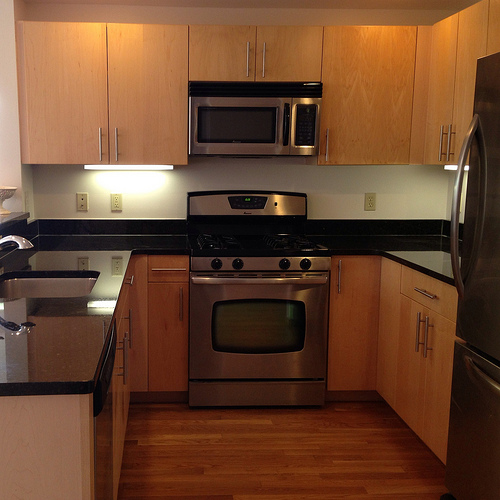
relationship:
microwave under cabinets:
[185, 82, 323, 158] [181, 27, 323, 87]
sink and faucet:
[1, 272, 97, 301] [0, 225, 39, 257]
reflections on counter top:
[89, 297, 117, 317] [2, 221, 464, 400]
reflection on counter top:
[89, 297, 117, 317] [2, 221, 464, 400]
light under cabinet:
[81, 162, 180, 172] [13, 22, 189, 170]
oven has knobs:
[183, 190, 333, 411] [202, 256, 323, 274]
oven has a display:
[183, 190, 333, 411] [239, 195, 256, 203]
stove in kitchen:
[183, 190, 333, 411] [0, 0, 499, 499]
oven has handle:
[183, 190, 333, 411] [187, 273, 328, 285]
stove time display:
[183, 190, 333, 411] [239, 195, 256, 203]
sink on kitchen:
[1, 272, 97, 301] [0, 0, 499, 499]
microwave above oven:
[185, 82, 323, 158] [183, 190, 333, 411]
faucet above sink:
[0, 225, 39, 257] [1, 272, 97, 301]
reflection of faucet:
[2, 302, 42, 338] [0, 225, 39, 257]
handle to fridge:
[451, 109, 478, 299] [435, 56, 500, 357]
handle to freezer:
[457, 357, 499, 395] [448, 343, 497, 499]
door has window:
[185, 270, 334, 386] [211, 299, 306, 350]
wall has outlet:
[33, 166, 456, 220] [111, 193, 124, 216]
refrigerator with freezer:
[435, 56, 500, 357] [448, 343, 497, 499]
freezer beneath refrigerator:
[448, 343, 497, 499] [435, 56, 500, 357]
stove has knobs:
[183, 190, 333, 411] [202, 256, 323, 274]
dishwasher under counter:
[93, 326, 127, 499] [3, 233, 134, 401]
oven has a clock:
[183, 190, 333, 411] [239, 195, 256, 203]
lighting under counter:
[81, 162, 180, 172] [28, 212, 189, 254]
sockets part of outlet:
[109, 188, 121, 213] [111, 193, 124, 216]